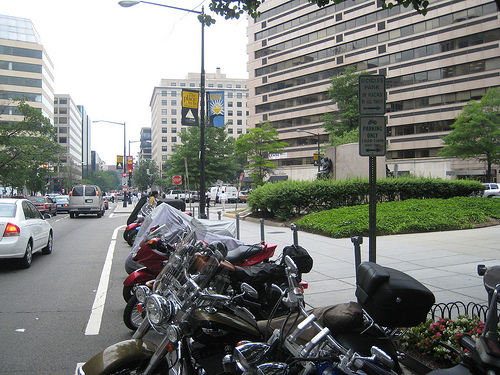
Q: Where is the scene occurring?
A: City street.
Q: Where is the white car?
A: To the left of the motorcycles.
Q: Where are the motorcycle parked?
A: In sides of road.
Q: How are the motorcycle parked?
A: In line.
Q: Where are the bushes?
A: In sidewalk.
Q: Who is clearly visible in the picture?
A: No one.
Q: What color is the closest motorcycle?
A: Brown.